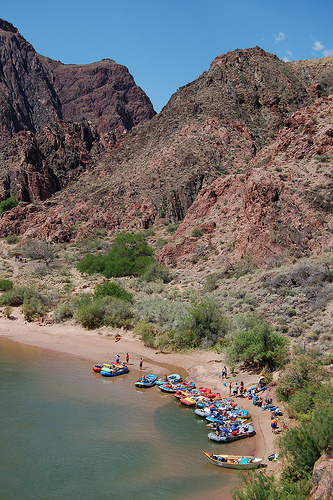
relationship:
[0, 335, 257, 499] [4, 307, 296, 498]
water near shore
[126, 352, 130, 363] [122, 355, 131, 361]
people in shirt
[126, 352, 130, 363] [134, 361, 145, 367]
people in pants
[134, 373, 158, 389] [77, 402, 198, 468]
boat on water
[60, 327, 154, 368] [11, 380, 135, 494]
sand near water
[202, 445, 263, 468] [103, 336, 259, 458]
boat in riverbank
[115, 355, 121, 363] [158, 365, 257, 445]
people near rafts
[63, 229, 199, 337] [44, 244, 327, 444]
trees near riverbank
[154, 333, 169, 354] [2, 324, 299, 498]
tree growing on riverbank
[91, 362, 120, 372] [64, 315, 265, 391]
boat at shore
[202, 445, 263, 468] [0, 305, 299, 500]
boat at riverbank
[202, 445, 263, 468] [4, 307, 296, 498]
boat at shore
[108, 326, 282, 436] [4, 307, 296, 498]
people at shore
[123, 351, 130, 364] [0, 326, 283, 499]
people at shore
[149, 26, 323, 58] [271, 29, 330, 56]
sky with clouds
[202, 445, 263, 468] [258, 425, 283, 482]
boat on sand